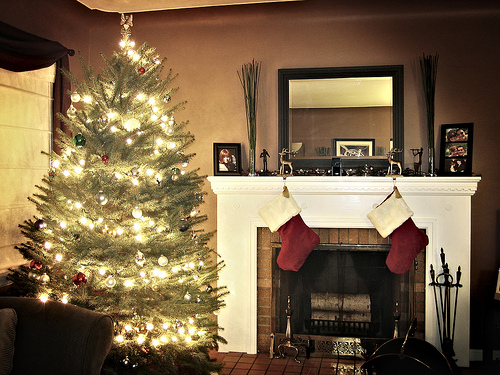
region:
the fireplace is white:
[208, 159, 481, 361]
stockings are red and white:
[260, 181, 480, 303]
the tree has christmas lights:
[20, 30, 261, 370]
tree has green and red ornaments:
[50, 56, 222, 324]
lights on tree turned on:
[55, 35, 252, 372]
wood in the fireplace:
[295, 279, 388, 328]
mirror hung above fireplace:
[268, 59, 413, 176]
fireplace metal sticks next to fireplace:
[426, 245, 471, 363]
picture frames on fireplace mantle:
[214, 112, 495, 178]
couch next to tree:
[0, 286, 132, 372]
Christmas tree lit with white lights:
[12, 5, 242, 367]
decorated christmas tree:
[14, 13, 217, 373]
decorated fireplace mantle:
[185, 43, 498, 343]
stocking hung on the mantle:
[189, 136, 497, 302]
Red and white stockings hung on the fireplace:
[203, 138, 481, 342]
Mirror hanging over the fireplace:
[185, 28, 486, 222]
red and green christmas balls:
[35, 101, 140, 192]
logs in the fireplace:
[208, 166, 478, 356]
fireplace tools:
[405, 233, 482, 369]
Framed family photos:
[431, 113, 479, 185]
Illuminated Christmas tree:
[18, 9, 226, 369]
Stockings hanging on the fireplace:
[260, 185, 436, 274]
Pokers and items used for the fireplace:
[425, 250, 475, 359]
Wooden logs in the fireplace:
[306, 289, 378, 325]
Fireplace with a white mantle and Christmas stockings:
[208, 175, 481, 364]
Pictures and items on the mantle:
[210, 119, 486, 176]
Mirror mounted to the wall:
[274, 65, 408, 170]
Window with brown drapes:
[0, 46, 75, 287]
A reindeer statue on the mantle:
[276, 147, 298, 173]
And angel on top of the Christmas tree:
[115, 12, 140, 41]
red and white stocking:
[380, 183, 426, 278]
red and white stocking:
[260, 175, 321, 275]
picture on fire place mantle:
[200, 131, 265, 172]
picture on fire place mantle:
[430, 113, 475, 179]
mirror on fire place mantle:
[266, 56, 406, 166]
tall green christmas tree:
[31, 10, 207, 325]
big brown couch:
[22, 285, 119, 361]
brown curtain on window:
[6, 21, 64, 108]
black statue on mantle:
[260, 138, 272, 179]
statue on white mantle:
[401, 137, 428, 180]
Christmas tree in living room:
[12, 12, 228, 372]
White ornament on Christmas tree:
[155, 250, 171, 271]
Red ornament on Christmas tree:
[70, 267, 87, 285]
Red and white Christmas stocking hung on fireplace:
[257, 187, 322, 272]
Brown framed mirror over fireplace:
[275, 62, 402, 168]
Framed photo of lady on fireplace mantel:
[208, 140, 243, 172]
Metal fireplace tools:
[422, 246, 463, 366]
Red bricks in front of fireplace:
[210, 345, 357, 374]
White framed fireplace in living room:
[202, 170, 478, 366]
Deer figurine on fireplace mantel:
[382, 147, 406, 173]